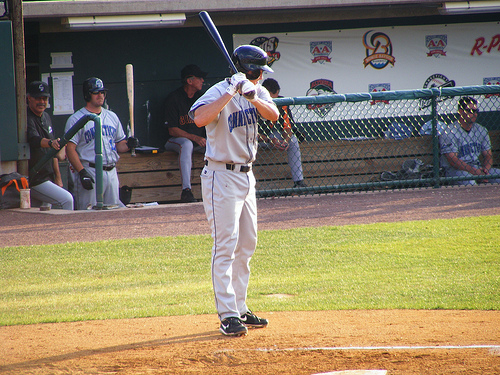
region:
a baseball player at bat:
[188, 6, 281, 340]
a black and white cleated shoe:
[220, 315, 247, 336]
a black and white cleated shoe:
[239, 313, 267, 329]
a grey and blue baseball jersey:
[189, 78, 279, 166]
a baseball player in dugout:
[64, 64, 137, 209]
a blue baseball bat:
[199, 8, 237, 75]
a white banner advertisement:
[230, 20, 499, 122]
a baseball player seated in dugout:
[441, 98, 498, 184]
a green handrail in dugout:
[31, 112, 103, 208]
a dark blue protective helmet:
[231, 44, 273, 74]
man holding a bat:
[190, 8, 282, 335]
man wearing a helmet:
[185, 17, 290, 337]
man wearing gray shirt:
[180, 15, 281, 340]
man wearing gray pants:
[190, 8, 271, 344]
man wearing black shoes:
[126, 10, 282, 353]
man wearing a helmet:
[83, 71, 118, 197]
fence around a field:
[335, 91, 395, 181]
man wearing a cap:
[27, 72, 67, 207]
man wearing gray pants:
[30, 75, 77, 215]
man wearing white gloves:
[166, 10, 313, 373]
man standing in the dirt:
[186, 43, 288, 337]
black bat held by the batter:
[198, 5, 255, 105]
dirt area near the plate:
[1, 300, 497, 373]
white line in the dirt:
[211, 342, 497, 360]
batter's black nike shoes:
[213, 307, 274, 342]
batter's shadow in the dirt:
[0, 325, 236, 372]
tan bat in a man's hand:
[122, 58, 139, 146]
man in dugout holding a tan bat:
[61, 68, 139, 213]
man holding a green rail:
[22, 73, 84, 220]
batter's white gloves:
[223, 70, 258, 102]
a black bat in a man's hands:
[200, 6, 248, 90]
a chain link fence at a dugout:
[248, 81, 498, 198]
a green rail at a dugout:
[26, 107, 108, 212]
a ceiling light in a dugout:
[61, 12, 190, 30]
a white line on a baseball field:
[226, 339, 498, 353]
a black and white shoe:
[217, 316, 250, 339]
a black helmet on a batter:
[229, 42, 275, 80]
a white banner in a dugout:
[230, 17, 498, 124]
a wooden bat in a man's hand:
[123, 58, 139, 139]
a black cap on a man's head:
[180, 61, 212, 81]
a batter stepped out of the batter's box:
[188, 7, 278, 338]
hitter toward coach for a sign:
[194, 13, 281, 336]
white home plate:
[312, 367, 385, 374]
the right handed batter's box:
[230, 346, 498, 366]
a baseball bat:
[198, 10, 253, 95]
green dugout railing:
[238, 87, 498, 194]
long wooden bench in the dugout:
[114, 133, 497, 201]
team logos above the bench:
[242, 35, 498, 112]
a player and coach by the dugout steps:
[32, 63, 137, 211]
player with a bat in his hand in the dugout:
[65, 65, 135, 216]